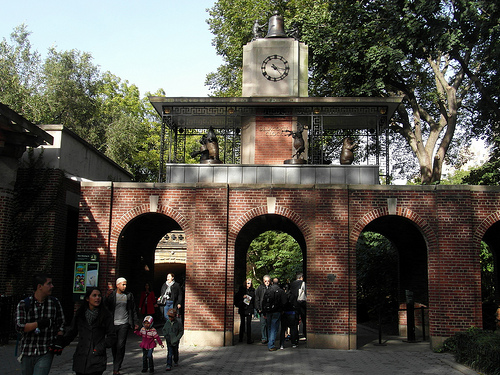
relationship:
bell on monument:
[254, 3, 295, 43] [233, 8, 329, 190]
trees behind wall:
[231, 2, 499, 180] [46, 130, 497, 354]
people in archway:
[233, 266, 305, 346] [226, 183, 308, 354]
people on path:
[233, 266, 305, 346] [177, 341, 452, 374]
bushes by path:
[438, 320, 499, 373] [177, 341, 452, 374]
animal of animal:
[188, 126, 223, 164] [203, 126, 221, 147]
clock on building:
[263, 52, 285, 85] [161, 20, 386, 189]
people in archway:
[116, 257, 180, 333] [107, 203, 198, 346]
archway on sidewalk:
[355, 211, 427, 350] [345, 317, 452, 370]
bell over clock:
[254, 3, 295, 43] [263, 52, 285, 85]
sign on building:
[65, 235, 104, 303] [161, 20, 386, 189]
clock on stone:
[263, 52, 285, 85] [246, 37, 314, 101]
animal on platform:
[188, 126, 223, 164] [165, 153, 382, 188]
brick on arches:
[206, 194, 225, 277] [112, 201, 451, 269]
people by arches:
[10, 274, 191, 363] [112, 201, 451, 269]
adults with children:
[9, 266, 133, 363] [133, 306, 184, 371]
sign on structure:
[65, 235, 104, 303] [53, 171, 264, 346]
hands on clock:
[269, 66, 288, 74] [263, 52, 285, 85]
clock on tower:
[263, 52, 285, 85] [246, 3, 295, 201]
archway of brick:
[226, 183, 308, 354] [206, 194, 225, 277]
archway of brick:
[107, 203, 198, 346] [206, 194, 225, 277]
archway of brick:
[355, 211, 427, 350] [206, 194, 225, 277]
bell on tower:
[254, 3, 295, 43] [246, 3, 295, 201]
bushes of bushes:
[438, 320, 499, 373] [438, 320, 499, 373]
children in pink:
[133, 315, 165, 372] [139, 336, 156, 349]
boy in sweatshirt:
[166, 298, 184, 362] [164, 313, 179, 345]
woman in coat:
[79, 282, 106, 363] [72, 305, 111, 359]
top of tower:
[246, 28, 314, 57] [246, 3, 295, 201]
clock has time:
[263, 52, 285, 85] [270, 66, 293, 81]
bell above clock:
[254, 3, 295, 43] [263, 52, 285, 85]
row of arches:
[77, 258, 471, 307] [112, 201, 451, 269]